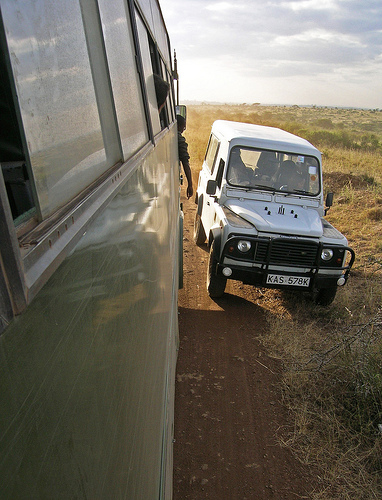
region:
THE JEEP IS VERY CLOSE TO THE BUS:
[185, 105, 352, 316]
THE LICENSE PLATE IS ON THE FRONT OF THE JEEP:
[259, 262, 318, 291]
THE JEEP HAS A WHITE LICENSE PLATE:
[260, 267, 315, 287]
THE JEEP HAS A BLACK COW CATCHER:
[210, 222, 365, 295]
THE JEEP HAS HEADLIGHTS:
[229, 231, 342, 262]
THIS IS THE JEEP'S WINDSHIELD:
[221, 143, 326, 196]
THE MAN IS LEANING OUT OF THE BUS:
[167, 104, 193, 206]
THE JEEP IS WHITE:
[194, 104, 357, 325]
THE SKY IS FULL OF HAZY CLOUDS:
[156, 0, 378, 123]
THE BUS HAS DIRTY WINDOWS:
[0, 0, 183, 341]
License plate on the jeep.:
[258, 271, 315, 292]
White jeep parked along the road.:
[189, 115, 353, 295]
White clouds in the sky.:
[230, 14, 336, 70]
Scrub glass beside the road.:
[269, 304, 344, 463]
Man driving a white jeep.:
[274, 156, 311, 192]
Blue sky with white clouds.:
[300, 56, 370, 93]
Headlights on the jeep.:
[231, 232, 261, 254]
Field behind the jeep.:
[307, 110, 374, 133]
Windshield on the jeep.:
[217, 147, 322, 187]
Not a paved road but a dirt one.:
[176, 316, 245, 451]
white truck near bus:
[201, 95, 341, 340]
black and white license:
[249, 264, 308, 288]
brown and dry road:
[183, 321, 264, 452]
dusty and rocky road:
[183, 321, 263, 450]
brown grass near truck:
[268, 323, 371, 493]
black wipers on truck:
[243, 163, 314, 187]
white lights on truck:
[244, 227, 344, 277]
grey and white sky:
[178, 20, 307, 99]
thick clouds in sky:
[206, 30, 340, 79]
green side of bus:
[116, 152, 189, 315]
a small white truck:
[191, 118, 354, 305]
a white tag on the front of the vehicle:
[262, 271, 307, 285]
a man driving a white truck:
[191, 117, 352, 303]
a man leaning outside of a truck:
[174, 113, 193, 200]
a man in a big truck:
[174, 114, 194, 200]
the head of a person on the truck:
[152, 73, 172, 115]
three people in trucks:
[1, 1, 380, 499]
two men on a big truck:
[2, 22, 194, 498]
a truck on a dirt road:
[2, 1, 194, 499]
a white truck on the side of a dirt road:
[192, 119, 355, 308]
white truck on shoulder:
[201, 96, 328, 309]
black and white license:
[256, 268, 328, 299]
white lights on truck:
[219, 240, 330, 256]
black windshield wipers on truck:
[227, 163, 302, 203]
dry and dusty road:
[167, 347, 263, 489]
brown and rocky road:
[202, 361, 282, 481]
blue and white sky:
[228, 32, 317, 79]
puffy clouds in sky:
[225, 36, 310, 80]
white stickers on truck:
[298, 155, 320, 182]